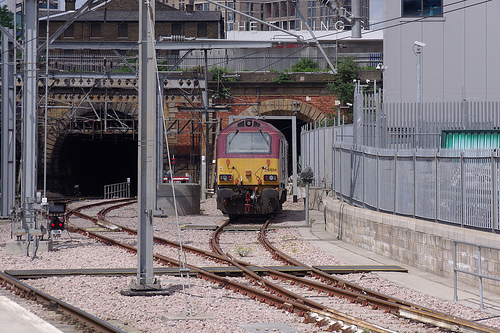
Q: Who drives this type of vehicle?
A: Conductor.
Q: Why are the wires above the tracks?
A: For electricity.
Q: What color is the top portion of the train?
A: Red.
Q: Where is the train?
A: On the tracks.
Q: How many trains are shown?
A: One.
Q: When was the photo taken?
A: Daytime.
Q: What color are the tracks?
A: Brown.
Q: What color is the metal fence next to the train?
A: Gray.